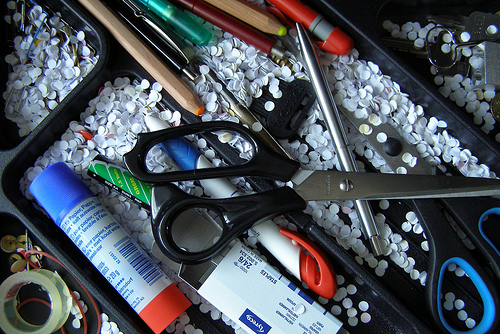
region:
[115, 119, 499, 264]
scissors with black handles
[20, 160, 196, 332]
stick of glue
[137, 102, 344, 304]
ink pen with a white barrel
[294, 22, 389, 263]
silver colored pen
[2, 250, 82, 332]
roll of clear tape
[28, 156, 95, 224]
blue cap on a glue stick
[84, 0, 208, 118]
orange color pencil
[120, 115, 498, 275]
scissors with black eye ring handle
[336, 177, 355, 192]
screw of the scissors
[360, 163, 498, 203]
blade of the scissors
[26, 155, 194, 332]
a glue stick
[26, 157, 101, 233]
blue lid of the glue stick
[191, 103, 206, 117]
lead of the pencil color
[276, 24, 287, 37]
lead of the pencil color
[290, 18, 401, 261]
a ballpen next to the scissors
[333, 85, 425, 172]
part of the blade of the scissors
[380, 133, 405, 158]
screw of the scissors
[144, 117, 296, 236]
the handle is black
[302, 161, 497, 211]
the blade is silver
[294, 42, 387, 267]
the pen is silver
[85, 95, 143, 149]
the dots are white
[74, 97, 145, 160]
the dots are paper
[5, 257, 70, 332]
the tape is clear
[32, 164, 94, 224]
the glue stick cap is blue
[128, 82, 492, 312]
two pairs of scissors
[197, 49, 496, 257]
pen is below scissors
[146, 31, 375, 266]
scissors above the pen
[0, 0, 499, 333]
the white paper holes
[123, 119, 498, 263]
the scissors with the black handle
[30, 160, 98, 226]
the blue colored cap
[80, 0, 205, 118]
the pencil with an orange tip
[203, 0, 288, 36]
the pencil with a yellow tip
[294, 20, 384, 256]
the all silver pen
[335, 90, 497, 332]
the scissors with a black and blue handle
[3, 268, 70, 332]
the roll of clear tape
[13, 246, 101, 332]
the thin red rubber bands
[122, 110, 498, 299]
the pen under the scissors with a black handle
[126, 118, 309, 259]
Black handle on scissors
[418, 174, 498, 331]
Black and blue handle on scissors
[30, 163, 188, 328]
Glue stick in a tray